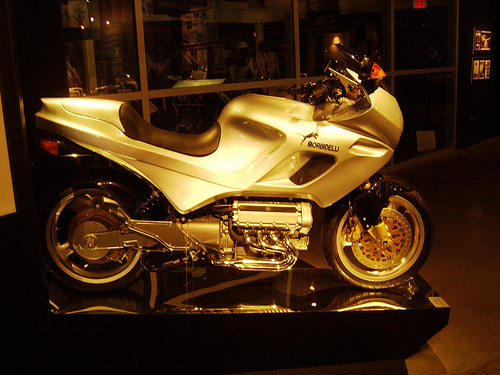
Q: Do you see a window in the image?
A: Yes, there is a window.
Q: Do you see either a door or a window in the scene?
A: Yes, there is a window.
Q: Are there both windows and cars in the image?
A: No, there is a window but no cars.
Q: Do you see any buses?
A: No, there are no buses.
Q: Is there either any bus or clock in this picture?
A: No, there are no buses or clocks.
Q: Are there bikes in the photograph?
A: Yes, there is a bike.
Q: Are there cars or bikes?
A: Yes, there is a bike.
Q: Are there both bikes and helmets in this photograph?
A: No, there is a bike but no helmets.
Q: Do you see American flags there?
A: No, there are no American flags.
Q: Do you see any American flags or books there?
A: No, there are no American flags or books.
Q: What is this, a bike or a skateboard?
A: This is a bike.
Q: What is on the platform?
A: The bike is on the platform.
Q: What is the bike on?
A: The bike is on the platform.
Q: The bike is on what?
A: The bike is on the platform.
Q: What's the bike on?
A: The bike is on the platform.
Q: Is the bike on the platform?
A: Yes, the bike is on the platform.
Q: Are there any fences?
A: No, there are no fences.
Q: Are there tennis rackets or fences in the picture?
A: No, there are no fences or tennis rackets.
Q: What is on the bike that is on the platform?
A: The logo is on the bike.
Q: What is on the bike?
A: The logo is on the bike.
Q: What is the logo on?
A: The logo is on the bike.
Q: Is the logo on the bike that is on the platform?
A: Yes, the logo is on the bike.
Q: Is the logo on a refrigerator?
A: No, the logo is on the bike.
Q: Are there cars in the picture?
A: No, there are no cars.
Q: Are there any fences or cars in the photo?
A: No, there are no cars or fences.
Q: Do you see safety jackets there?
A: No, there are no safety jackets.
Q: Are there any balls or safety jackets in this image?
A: No, there are no safety jackets or balls.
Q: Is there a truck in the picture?
A: No, there are no trucks.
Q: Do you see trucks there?
A: No, there are no trucks.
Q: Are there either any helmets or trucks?
A: No, there are no trucks or helmets.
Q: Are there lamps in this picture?
A: No, there are no lamps.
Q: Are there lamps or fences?
A: No, there are no lamps or fences.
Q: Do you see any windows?
A: Yes, there is a window.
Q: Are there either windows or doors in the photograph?
A: Yes, there is a window.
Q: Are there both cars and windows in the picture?
A: No, there is a window but no cars.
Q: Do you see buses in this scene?
A: No, there are no buses.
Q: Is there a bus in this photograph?
A: No, there are no buses.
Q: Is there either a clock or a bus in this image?
A: No, there are no buses or clocks.